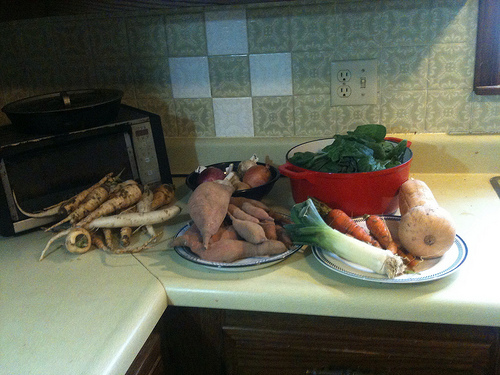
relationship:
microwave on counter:
[1, 97, 171, 232] [1, 137, 495, 372]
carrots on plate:
[318, 200, 401, 255] [303, 209, 473, 293]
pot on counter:
[288, 162, 403, 202] [434, 173, 498, 320]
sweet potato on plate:
[225, 217, 265, 244] [179, 252, 289, 271]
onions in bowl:
[199, 160, 268, 187] [191, 160, 277, 197]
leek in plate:
[296, 203, 404, 270] [316, 215, 486, 315]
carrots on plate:
[329, 200, 402, 267] [409, 228, 481, 300]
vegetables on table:
[81, 119, 452, 274] [114, 170, 500, 375]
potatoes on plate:
[166, 180, 285, 260] [170, 189, 309, 279]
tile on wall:
[242, 49, 294, 99] [2, 10, 494, 134]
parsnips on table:
[27, 165, 195, 262] [7, 170, 493, 363]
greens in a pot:
[309, 125, 406, 174] [277, 135, 412, 215]